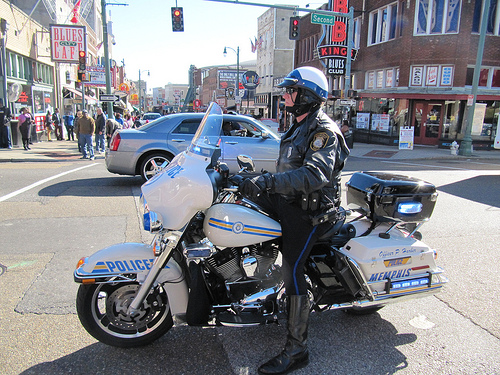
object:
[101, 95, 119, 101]
black/white sign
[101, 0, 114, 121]
pole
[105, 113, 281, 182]
silver car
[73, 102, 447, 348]
motorcycle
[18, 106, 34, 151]
woman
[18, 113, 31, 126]
shirt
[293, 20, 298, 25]
traffic signal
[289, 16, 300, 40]
traffic light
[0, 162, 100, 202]
line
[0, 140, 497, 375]
street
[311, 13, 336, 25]
sign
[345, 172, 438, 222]
box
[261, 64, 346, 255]
motorcycle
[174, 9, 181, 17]
signal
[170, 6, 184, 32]
light